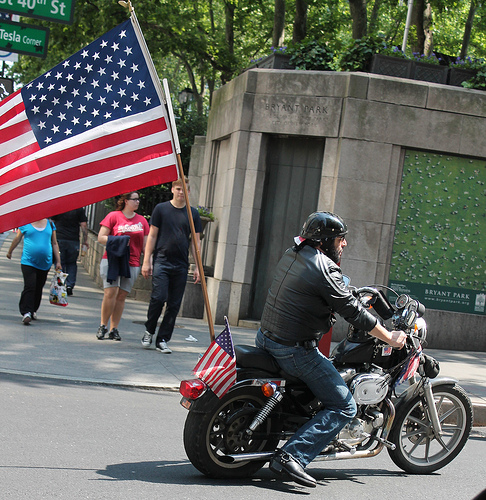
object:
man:
[255, 208, 403, 487]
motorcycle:
[179, 283, 472, 481]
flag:
[1, 19, 181, 237]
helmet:
[301, 210, 344, 248]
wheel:
[385, 380, 474, 473]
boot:
[265, 446, 320, 488]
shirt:
[255, 241, 381, 346]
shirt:
[98, 212, 152, 267]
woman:
[94, 190, 158, 348]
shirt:
[19, 217, 54, 272]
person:
[7, 214, 60, 327]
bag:
[49, 271, 68, 307]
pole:
[160, 76, 216, 345]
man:
[138, 173, 204, 356]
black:
[142, 200, 200, 340]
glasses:
[127, 193, 143, 206]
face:
[126, 193, 142, 215]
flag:
[192, 313, 240, 400]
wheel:
[182, 380, 284, 482]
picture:
[384, 143, 484, 317]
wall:
[175, 66, 485, 350]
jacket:
[102, 234, 133, 285]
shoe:
[140, 330, 155, 350]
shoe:
[155, 336, 175, 353]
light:
[178, 379, 206, 404]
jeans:
[252, 326, 357, 458]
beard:
[332, 251, 344, 265]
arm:
[98, 215, 119, 250]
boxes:
[358, 51, 410, 80]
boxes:
[240, 48, 319, 75]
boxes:
[447, 65, 484, 89]